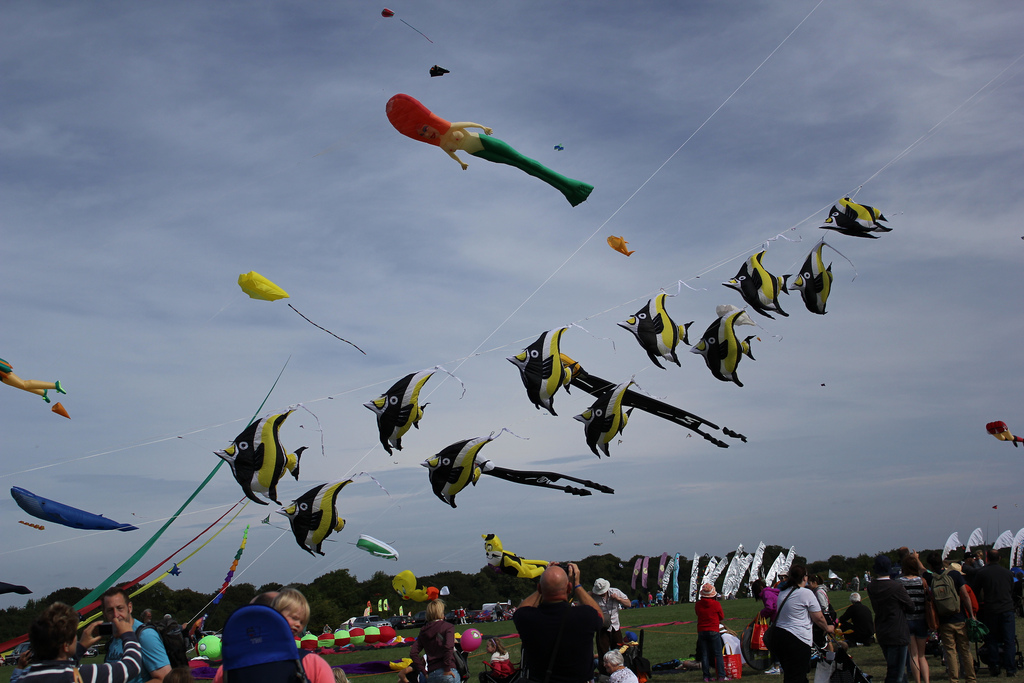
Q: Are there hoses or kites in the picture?
A: Yes, there is a kite.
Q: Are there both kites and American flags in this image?
A: No, there is a kite but no American flags.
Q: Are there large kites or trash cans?
A: Yes, there is a large kite.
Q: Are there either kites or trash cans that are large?
A: Yes, the kite is large.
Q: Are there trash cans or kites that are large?
A: Yes, the kite is large.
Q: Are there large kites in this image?
A: Yes, there is a large kite.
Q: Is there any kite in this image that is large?
A: Yes, there is a kite that is large.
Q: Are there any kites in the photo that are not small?
A: Yes, there is a large kite.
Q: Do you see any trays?
A: No, there are no trays.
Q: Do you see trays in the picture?
A: No, there are no trays.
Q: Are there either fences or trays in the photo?
A: No, there are no trays or fences.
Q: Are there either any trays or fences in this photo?
A: No, there are no trays or fences.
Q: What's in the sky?
A: The kite is in the sky.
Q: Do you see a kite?
A: Yes, there is a kite.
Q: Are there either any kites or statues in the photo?
A: Yes, there is a kite.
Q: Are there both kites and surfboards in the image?
A: No, there is a kite but no surfboards.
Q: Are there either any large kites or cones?
A: Yes, there is a large kite.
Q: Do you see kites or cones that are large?
A: Yes, the kite is large.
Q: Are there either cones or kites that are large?
A: Yes, the kite is large.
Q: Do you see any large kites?
A: Yes, there is a large kite.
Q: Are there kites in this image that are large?
A: Yes, there is a kite that is large.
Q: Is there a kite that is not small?
A: Yes, there is a large kite.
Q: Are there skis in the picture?
A: No, there are no skis.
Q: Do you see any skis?
A: No, there are no skis.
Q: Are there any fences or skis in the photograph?
A: No, there are no skis or fences.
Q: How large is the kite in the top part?
A: The kite is large.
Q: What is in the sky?
A: The kite is in the sky.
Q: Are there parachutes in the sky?
A: No, there is a kite in the sky.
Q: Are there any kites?
A: Yes, there is a kite.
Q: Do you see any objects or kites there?
A: Yes, there is a kite.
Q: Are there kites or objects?
A: Yes, there is a kite.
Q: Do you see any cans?
A: No, there are no cans.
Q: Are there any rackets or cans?
A: No, there are no cans or rackets.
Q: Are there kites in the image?
A: Yes, there is a kite.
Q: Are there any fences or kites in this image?
A: Yes, there is a kite.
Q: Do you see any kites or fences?
A: Yes, there is a kite.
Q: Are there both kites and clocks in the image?
A: No, there is a kite but no clocks.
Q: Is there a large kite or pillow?
A: Yes, there is a large kite.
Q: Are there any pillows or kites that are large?
A: Yes, the kite is large.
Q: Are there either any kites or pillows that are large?
A: Yes, the kite is large.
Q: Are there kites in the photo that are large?
A: Yes, there is a kite that is large.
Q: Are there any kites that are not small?
A: Yes, there is a large kite.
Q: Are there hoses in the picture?
A: No, there are no hoses.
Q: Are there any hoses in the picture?
A: No, there are no hoses.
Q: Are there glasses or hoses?
A: No, there are no hoses or glasses.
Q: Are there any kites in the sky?
A: Yes, there is a kite in the sky.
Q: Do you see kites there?
A: Yes, there is a kite.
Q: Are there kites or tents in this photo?
A: Yes, there is a kite.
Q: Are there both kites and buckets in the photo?
A: No, there is a kite but no buckets.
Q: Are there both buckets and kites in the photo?
A: No, there is a kite but no buckets.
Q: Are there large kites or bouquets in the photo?
A: Yes, there is a large kite.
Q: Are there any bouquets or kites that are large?
A: Yes, the kite is large.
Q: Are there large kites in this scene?
A: Yes, there is a large kite.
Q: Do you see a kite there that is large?
A: Yes, there is a kite that is large.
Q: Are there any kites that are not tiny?
A: Yes, there is a large kite.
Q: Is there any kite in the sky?
A: Yes, there is a kite in the sky.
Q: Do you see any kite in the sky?
A: Yes, there is a kite in the sky.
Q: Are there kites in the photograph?
A: Yes, there is a kite.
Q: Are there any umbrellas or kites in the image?
A: Yes, there is a kite.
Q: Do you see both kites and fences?
A: No, there is a kite but no fences.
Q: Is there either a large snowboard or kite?
A: Yes, there is a large kite.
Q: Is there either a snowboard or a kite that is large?
A: Yes, the kite is large.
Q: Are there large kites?
A: Yes, there is a large kite.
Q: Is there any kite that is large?
A: Yes, there is a kite that is large.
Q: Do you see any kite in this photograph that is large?
A: Yes, there is a kite that is large.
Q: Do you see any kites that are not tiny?
A: Yes, there is a large kite.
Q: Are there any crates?
A: No, there are no crates.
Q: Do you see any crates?
A: No, there are no crates.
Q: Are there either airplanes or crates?
A: No, there are no crates or airplanes.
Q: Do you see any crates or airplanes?
A: No, there are no crates or airplanes.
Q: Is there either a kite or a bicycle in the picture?
A: Yes, there is a kite.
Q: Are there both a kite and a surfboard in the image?
A: No, there is a kite but no surfboards.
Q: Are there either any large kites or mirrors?
A: Yes, there is a large kite.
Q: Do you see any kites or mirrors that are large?
A: Yes, the kite is large.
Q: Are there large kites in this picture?
A: Yes, there is a large kite.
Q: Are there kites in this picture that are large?
A: Yes, there is a large kite.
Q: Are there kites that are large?
A: Yes, there is a kite that is large.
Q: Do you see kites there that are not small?
A: Yes, there is a large kite.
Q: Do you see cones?
A: No, there are no cones.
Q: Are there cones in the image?
A: No, there are no cones.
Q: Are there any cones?
A: No, there are no cones.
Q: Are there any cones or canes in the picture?
A: No, there are no cones or canes.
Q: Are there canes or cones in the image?
A: No, there are no cones or canes.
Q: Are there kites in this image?
A: Yes, there is a kite.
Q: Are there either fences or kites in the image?
A: Yes, there is a kite.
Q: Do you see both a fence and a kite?
A: No, there is a kite but no fences.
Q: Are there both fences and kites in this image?
A: No, there is a kite but no fences.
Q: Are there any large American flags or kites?
A: Yes, there is a large kite.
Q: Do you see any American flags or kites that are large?
A: Yes, the kite is large.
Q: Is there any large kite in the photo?
A: Yes, there is a large kite.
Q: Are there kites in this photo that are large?
A: Yes, there is a kite that is large.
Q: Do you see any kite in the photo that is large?
A: Yes, there is a kite that is large.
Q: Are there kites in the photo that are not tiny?
A: Yes, there is a large kite.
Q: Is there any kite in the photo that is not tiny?
A: Yes, there is a large kite.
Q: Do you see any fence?
A: No, there are no fences.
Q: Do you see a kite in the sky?
A: Yes, there is a kite in the sky.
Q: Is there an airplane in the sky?
A: No, there is a kite in the sky.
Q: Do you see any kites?
A: Yes, there is a kite.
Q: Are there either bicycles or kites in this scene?
A: Yes, there is a kite.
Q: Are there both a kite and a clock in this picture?
A: No, there is a kite but no clocks.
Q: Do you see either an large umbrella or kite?
A: Yes, there is a large kite.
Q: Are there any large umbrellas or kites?
A: Yes, there is a large kite.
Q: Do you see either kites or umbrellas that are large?
A: Yes, the kite is large.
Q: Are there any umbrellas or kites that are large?
A: Yes, the kite is large.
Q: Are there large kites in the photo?
A: Yes, there is a large kite.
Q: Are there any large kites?
A: Yes, there is a large kite.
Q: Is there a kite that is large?
A: Yes, there is a kite that is large.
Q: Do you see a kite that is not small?
A: Yes, there is a large kite.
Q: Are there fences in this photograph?
A: No, there are no fences.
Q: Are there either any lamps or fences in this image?
A: No, there are no fences or lamps.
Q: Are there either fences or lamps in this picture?
A: No, there are no fences or lamps.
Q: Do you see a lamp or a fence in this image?
A: No, there are no fences or lamps.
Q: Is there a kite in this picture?
A: Yes, there is a kite.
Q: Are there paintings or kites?
A: Yes, there is a kite.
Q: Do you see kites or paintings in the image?
A: Yes, there is a kite.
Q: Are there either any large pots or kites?
A: Yes, there is a large kite.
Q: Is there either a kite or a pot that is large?
A: Yes, the kite is large.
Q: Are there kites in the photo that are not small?
A: Yes, there is a large kite.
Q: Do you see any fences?
A: No, there are no fences.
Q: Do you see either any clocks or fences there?
A: No, there are no fences or clocks.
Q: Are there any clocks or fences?
A: No, there are no fences or clocks.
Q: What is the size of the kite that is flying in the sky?
A: The kite is large.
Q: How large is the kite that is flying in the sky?
A: The kite is large.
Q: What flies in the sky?
A: The kite flies in the sky.